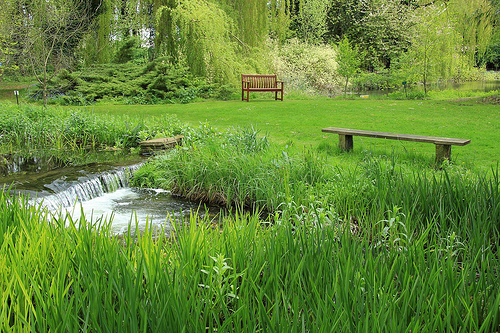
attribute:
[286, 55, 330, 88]
bush — white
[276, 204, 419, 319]
grass — tall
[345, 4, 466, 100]
bush — large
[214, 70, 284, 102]
bench — wooden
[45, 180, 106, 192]
waterfall — small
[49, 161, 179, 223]
pond — little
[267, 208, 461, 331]
grass — green, blades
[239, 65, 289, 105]
bench — shadow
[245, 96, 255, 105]
leg — bench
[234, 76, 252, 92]
armrest — bench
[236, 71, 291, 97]
bench — brown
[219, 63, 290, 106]
bench — wood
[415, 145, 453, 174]
blocks — concrete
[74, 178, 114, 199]
waterfall — small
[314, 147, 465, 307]
weeds — tall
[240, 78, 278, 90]
back — slatted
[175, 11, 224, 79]
willows — weeping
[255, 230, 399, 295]
grass — bright, green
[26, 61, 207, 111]
shrubs — shorter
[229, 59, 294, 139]
bench — brown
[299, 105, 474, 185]
bench — long